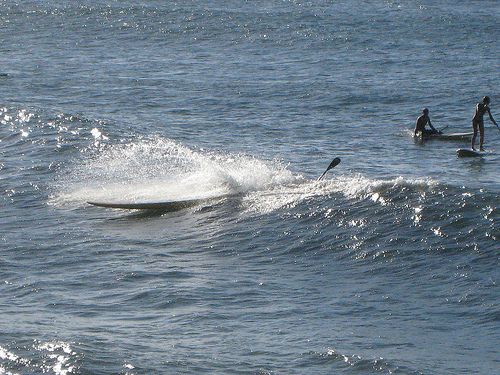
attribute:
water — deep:
[82, 29, 197, 134]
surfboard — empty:
[77, 172, 254, 227]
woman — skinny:
[388, 73, 489, 175]